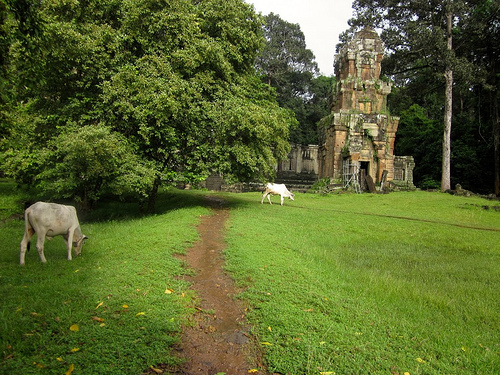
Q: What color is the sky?
A: Gray.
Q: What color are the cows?
A: White.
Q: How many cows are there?
A: Two.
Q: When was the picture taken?
A: Daytime.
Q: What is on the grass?
A: Cows.